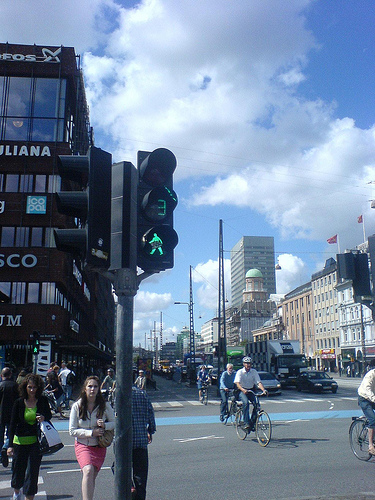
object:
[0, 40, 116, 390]
building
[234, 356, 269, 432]
man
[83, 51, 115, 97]
cloud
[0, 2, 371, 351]
sky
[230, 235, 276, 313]
skyscraper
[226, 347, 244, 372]
truck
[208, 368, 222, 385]
cars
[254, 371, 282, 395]
car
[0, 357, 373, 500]
street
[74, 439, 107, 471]
pink skirt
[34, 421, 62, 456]
bag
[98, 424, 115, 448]
bag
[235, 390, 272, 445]
bicycle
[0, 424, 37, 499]
crosswalk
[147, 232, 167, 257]
green light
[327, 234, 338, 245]
flag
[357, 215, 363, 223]
flag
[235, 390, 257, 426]
pants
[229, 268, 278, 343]
building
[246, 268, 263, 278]
dome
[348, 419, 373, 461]
tire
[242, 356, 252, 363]
helmet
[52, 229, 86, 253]
traffic light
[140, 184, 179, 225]
street light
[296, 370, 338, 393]
car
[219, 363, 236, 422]
person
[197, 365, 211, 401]
person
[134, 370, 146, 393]
person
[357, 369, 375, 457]
person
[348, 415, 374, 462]
bike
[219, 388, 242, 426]
bike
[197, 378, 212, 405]
bike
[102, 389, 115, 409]
bike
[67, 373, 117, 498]
woman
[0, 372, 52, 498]
woman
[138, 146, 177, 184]
traffic light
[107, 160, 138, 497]
pole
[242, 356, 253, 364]
cap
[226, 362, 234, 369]
hair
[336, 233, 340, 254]
pole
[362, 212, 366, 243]
pole